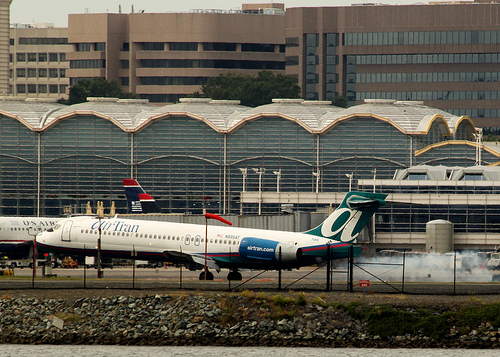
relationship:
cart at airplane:
[3, 245, 90, 280] [37, 179, 389, 280]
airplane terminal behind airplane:
[5, 92, 499, 242] [37, 179, 389, 280]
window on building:
[347, 32, 352, 49] [282, 6, 498, 131]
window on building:
[355, 74, 362, 82] [282, 6, 498, 131]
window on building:
[389, 91, 397, 102] [282, 6, 498, 131]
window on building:
[400, 32, 408, 47] [282, 6, 498, 131]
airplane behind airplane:
[0, 177, 162, 258] [37, 179, 389, 280]